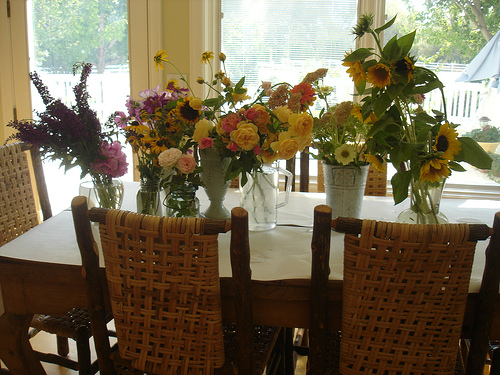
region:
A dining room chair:
[70, 194, 292, 373]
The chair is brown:
[71, 194, 285, 374]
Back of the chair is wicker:
[101, 207, 225, 374]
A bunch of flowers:
[4, 18, 496, 185]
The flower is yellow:
[431, 122, 459, 159]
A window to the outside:
[27, 3, 132, 168]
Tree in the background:
[418, 0, 493, 62]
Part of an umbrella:
[458, 27, 498, 81]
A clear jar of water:
[237, 161, 289, 229]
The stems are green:
[92, 178, 117, 206]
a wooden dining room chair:
[71, 190, 287, 373]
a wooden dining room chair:
[307, 197, 497, 372]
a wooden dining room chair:
[0, 115, 124, 372]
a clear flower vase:
[77, 177, 126, 208]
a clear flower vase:
[135, 180, 162, 214]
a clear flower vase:
[162, 185, 199, 220]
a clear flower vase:
[238, 160, 292, 232]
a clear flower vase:
[397, 176, 452, 225]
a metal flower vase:
[322, 160, 369, 219]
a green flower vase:
[197, 150, 234, 218]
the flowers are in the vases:
[313, 107, 366, 206]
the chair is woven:
[132, 255, 180, 312]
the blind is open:
[256, 17, 306, 58]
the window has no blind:
[48, 15, 107, 77]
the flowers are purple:
[33, 73, 101, 139]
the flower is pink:
[215, 111, 241, 135]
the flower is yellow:
[425, 115, 463, 163]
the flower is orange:
[286, 76, 313, 110]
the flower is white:
[158, 146, 184, 168]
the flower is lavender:
[98, 138, 128, 174]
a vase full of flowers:
[339, 15, 493, 226]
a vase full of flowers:
[303, 66, 370, 220]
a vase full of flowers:
[219, 80, 317, 230]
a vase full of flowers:
[154, 43, 244, 230]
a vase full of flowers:
[7, 63, 128, 210]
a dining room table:
[0, 179, 498, 370]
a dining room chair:
[70, 195, 282, 373]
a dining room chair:
[308, 205, 497, 373]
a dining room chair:
[2, 140, 107, 374]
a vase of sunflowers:
[344, 16, 491, 222]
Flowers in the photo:
[22, 63, 313, 175]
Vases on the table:
[78, 164, 262, 228]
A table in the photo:
[255, 244, 305, 280]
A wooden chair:
[156, 237, 216, 351]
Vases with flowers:
[314, 148, 454, 221]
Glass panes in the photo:
[250, 9, 318, 79]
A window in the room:
[55, 22, 107, 109]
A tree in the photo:
[423, 3, 493, 69]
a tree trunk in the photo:
[90, 18, 120, 78]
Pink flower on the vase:
[91, 129, 131, 182]